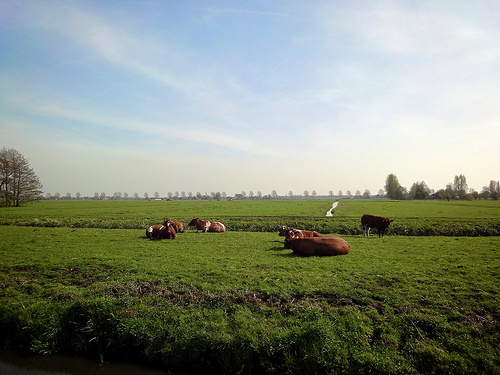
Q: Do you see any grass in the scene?
A: Yes, there is grass.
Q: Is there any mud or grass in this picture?
A: Yes, there is grass.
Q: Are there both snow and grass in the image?
A: No, there is grass but no snow.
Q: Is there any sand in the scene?
A: No, there is no sand.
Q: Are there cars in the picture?
A: No, there are no cars.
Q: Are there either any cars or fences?
A: No, there are no cars or fences.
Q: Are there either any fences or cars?
A: No, there are no cars or fences.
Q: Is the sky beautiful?
A: Yes, the sky is beautiful.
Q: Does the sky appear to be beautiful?
A: Yes, the sky is beautiful.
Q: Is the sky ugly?
A: No, the sky is beautiful.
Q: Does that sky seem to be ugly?
A: No, the sky is beautiful.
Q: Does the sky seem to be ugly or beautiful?
A: The sky is beautiful.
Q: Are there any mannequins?
A: No, there are no mannequins.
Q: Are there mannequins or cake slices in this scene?
A: No, there are no mannequins or cake slices.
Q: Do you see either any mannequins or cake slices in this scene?
A: No, there are no mannequins or cake slices.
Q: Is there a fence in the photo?
A: No, there are no fences.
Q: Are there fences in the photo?
A: No, there are no fences.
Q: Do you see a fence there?
A: No, there are no fences.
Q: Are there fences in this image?
A: No, there are no fences.